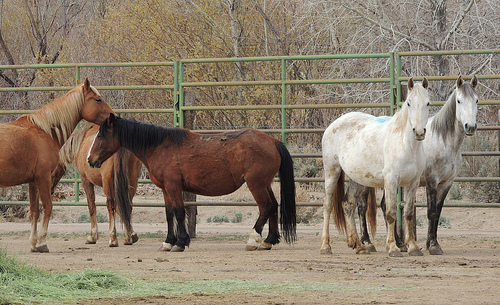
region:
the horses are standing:
[6, 64, 471, 274]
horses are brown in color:
[13, 73, 279, 274]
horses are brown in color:
[337, 95, 497, 200]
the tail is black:
[281, 148, 289, 242]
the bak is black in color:
[117, 113, 184, 148]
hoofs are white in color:
[247, 232, 274, 260]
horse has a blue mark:
[363, 106, 392, 135]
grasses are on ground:
[87, 253, 132, 298]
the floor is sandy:
[445, 256, 497, 293]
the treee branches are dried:
[178, 8, 270, 55]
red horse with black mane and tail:
[86, 116, 299, 252]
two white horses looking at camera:
[319, 73, 477, 252]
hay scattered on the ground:
[5, 261, 345, 301]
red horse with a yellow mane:
[5, 77, 108, 251]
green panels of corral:
[3, 47, 495, 214]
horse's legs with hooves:
[160, 206, 188, 254]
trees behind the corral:
[5, 3, 498, 208]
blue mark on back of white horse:
[368, 114, 391, 126]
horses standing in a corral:
[5, 74, 487, 266]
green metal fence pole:
[183, 54, 280, 63]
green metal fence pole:
[181, 78, 282, 88]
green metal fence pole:
[181, 102, 280, 114]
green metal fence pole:
[285, 50, 387, 60]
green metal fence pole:
[286, 74, 386, 86]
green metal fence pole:
[285, 125, 323, 135]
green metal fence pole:
[296, 199, 324, 209]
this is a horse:
[0, 68, 110, 140]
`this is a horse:
[91, 115, 285, 231]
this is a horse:
[321, 83, 437, 246]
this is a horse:
[422, 90, 487, 264]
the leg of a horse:
[86, 169, 107, 246]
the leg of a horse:
[37, 186, 54, 248]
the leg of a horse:
[29, 191, 43, 250]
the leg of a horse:
[106, 186, 120, 241]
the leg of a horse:
[129, 195, 137, 257]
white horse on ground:
[316, 80, 427, 255]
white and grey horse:
[426, 80, 484, 254]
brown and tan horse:
[1, 79, 113, 253]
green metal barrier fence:
[2, 46, 499, 208]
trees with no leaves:
[1, 1, 496, 154]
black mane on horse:
[113, 116, 185, 151]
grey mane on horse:
[433, 93, 457, 138]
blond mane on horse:
[28, 86, 83, 140]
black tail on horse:
[274, 142, 299, 242]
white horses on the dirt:
[293, 62, 488, 221]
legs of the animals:
[286, 166, 466, 266]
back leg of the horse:
[295, 157, 361, 257]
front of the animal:
[385, 143, 434, 186]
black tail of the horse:
[263, 125, 322, 235]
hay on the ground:
[5, 255, 142, 304]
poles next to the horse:
[186, 40, 343, 119]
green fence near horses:
[200, 18, 358, 133]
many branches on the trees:
[163, 10, 390, 50]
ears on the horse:
[386, 63, 440, 98]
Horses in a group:
[5, 76, 482, 273]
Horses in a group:
[316, 84, 489, 260]